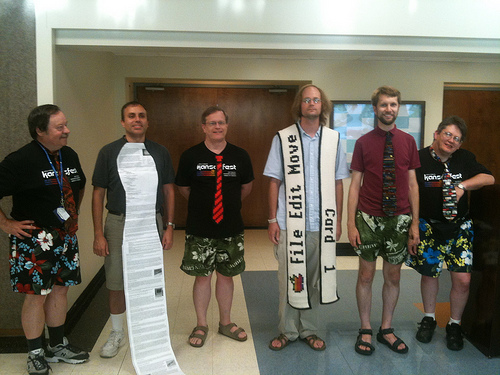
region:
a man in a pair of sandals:
[176, 310, 266, 363]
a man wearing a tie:
[372, 133, 407, 220]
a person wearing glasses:
[439, 123, 464, 156]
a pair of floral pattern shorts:
[8, 225, 81, 286]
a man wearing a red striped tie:
[203, 142, 238, 229]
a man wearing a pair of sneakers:
[12, 325, 93, 372]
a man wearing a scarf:
[281, 132, 321, 263]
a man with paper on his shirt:
[116, 147, 177, 298]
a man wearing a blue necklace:
[36, 140, 91, 203]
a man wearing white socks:
[93, 300, 143, 338]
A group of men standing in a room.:
[5, 63, 499, 373]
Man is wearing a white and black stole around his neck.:
[271, 113, 349, 366]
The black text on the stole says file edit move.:
[280, 128, 307, 268]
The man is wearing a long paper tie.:
[115, 135, 180, 373]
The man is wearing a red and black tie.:
[206, 152, 226, 227]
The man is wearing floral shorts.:
[3, 225, 90, 296]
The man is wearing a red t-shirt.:
[347, 120, 417, 218]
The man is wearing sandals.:
[185, 320, 256, 351]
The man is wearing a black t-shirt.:
[171, 136, 252, 241]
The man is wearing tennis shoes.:
[22, 340, 94, 372]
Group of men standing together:
[14, 91, 470, 267]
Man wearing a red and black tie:
[205, 150, 236, 229]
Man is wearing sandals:
[175, 313, 259, 351]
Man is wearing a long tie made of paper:
[97, 135, 198, 373]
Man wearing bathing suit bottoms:
[15, 228, 90, 290]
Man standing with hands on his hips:
[0, 87, 112, 374]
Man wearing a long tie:
[269, 121, 360, 312]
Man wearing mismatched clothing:
[351, 85, 422, 297]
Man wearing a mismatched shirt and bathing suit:
[410, 120, 497, 280]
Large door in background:
[97, 74, 338, 251]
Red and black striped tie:
[205, 153, 232, 224]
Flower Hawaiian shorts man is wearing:
[5, 223, 92, 300]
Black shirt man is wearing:
[172, 144, 256, 240]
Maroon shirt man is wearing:
[349, 125, 421, 223]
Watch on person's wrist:
[451, 180, 468, 196]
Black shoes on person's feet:
[410, 314, 470, 352]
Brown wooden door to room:
[130, 83, 324, 246]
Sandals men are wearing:
[180, 319, 412, 366]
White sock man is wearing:
[103, 311, 128, 335]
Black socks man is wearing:
[15, 322, 75, 353]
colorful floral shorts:
[6, 218, 89, 297]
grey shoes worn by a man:
[186, 313, 250, 357]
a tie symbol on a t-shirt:
[192, 143, 249, 226]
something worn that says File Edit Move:
[280, 129, 319, 309]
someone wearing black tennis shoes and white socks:
[413, 305, 469, 355]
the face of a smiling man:
[110, 98, 160, 140]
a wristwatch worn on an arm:
[452, 180, 471, 198]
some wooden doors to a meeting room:
[117, 69, 336, 242]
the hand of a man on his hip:
[2, 208, 40, 245]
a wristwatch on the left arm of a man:
[158, 212, 181, 236]